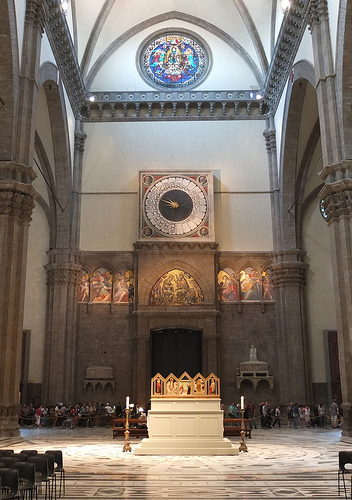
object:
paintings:
[114, 267, 134, 303]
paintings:
[91, 267, 112, 301]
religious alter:
[134, 372, 240, 457]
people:
[36, 405, 41, 425]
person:
[259, 399, 269, 428]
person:
[305, 405, 311, 423]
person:
[329, 399, 339, 428]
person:
[229, 403, 236, 417]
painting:
[141, 35, 207, 84]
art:
[217, 268, 238, 300]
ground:
[319, 88, 334, 103]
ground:
[295, 133, 316, 171]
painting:
[148, 269, 203, 306]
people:
[273, 406, 281, 427]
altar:
[134, 396, 238, 455]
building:
[0, 0, 352, 499]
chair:
[338, 450, 351, 497]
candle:
[126, 396, 130, 409]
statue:
[235, 345, 274, 392]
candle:
[241, 395, 244, 410]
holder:
[238, 409, 247, 451]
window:
[135, 26, 213, 91]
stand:
[239, 409, 248, 452]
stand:
[123, 409, 132, 452]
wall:
[79, 120, 275, 252]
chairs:
[0, 449, 65, 500]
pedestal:
[111, 414, 252, 439]